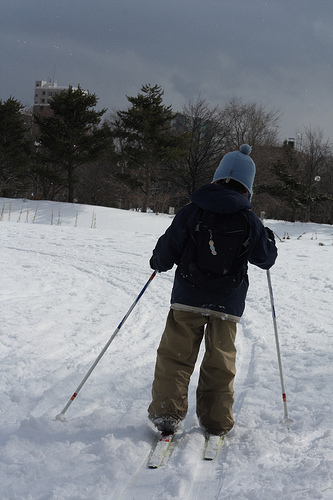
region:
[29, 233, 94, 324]
Te ground is covered in snow.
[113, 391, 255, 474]
Skis on persons feet.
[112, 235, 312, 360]
Ski poles in persons hands.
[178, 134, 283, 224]
Blue winter hat on head.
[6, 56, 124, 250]
Building behind the trees.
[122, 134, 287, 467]
A person skiing in the snow.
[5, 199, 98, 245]
Weeds sticking up out of the snow.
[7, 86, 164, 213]
Pine trees in the distance.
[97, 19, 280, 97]
Grey cloudy sky on a Winter day.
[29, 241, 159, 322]
Marks in the snow from people skiing.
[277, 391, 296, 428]
part of a hooker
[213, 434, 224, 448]
part of a board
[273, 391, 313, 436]
part of a hooker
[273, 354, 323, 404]
part of a hooker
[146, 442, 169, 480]
part of a board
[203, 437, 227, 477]
part of a board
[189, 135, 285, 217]
head of a person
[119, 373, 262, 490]
skis in the snow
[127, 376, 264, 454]
feet of the person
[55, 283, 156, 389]
ski pole next to person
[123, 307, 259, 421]
pants of the person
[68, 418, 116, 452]
shadow on the ground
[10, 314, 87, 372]
snow on the ground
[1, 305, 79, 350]
white snow on ground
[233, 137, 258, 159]
tip of the hat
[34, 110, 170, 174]
trees in the distance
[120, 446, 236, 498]
tracks in the snow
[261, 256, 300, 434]
ski poles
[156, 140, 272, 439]
a person wearing a blue jacket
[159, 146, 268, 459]
a person wearing skis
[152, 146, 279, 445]
a person wearing a blue ski hat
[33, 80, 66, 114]
a building in the back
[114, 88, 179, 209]
a pine tree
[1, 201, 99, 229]
a fence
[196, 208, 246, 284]
a black backpack on the person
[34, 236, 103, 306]
snow on the ground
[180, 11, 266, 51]
this is the sky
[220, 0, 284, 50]
the sky is blue in color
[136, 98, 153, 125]
the leaves are green in color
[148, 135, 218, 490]
this is a man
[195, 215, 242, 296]
this is a jacket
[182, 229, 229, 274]
the jacket is black in color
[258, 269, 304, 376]
this is a stick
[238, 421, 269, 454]
this is the snow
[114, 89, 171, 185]
this is a tree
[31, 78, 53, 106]
this is a building